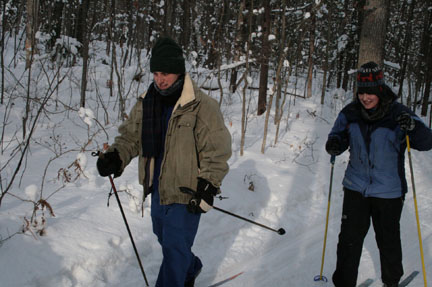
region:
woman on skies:
[314, 63, 430, 285]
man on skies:
[92, 42, 284, 285]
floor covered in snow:
[1, 26, 430, 285]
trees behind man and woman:
[1, 0, 428, 160]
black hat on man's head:
[150, 38, 183, 72]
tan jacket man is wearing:
[108, 78, 230, 208]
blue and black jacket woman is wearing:
[327, 102, 431, 198]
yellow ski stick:
[399, 132, 430, 285]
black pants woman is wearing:
[334, 190, 404, 285]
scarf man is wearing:
[141, 78, 187, 158]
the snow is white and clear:
[253, 63, 345, 280]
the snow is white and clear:
[220, 59, 295, 283]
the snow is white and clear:
[265, 160, 316, 270]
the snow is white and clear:
[249, 169, 303, 283]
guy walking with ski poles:
[77, 21, 270, 285]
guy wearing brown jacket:
[109, 33, 246, 226]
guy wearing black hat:
[127, 23, 230, 185]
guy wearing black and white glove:
[130, 31, 227, 286]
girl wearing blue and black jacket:
[319, 60, 424, 226]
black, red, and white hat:
[345, 48, 416, 124]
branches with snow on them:
[30, 75, 125, 199]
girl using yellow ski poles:
[320, 64, 430, 284]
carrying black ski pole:
[172, 171, 309, 256]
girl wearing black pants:
[310, 50, 401, 286]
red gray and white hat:
[347, 49, 395, 99]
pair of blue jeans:
[147, 201, 209, 282]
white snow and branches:
[1, 120, 73, 276]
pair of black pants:
[328, 192, 414, 285]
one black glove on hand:
[84, 138, 130, 181]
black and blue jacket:
[313, 118, 404, 214]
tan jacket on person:
[152, 117, 219, 191]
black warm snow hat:
[135, 35, 188, 76]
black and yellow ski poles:
[192, 146, 419, 281]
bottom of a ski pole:
[308, 252, 328, 285]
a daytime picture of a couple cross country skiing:
[0, 0, 430, 285]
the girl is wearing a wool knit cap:
[353, 61, 398, 112]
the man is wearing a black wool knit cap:
[148, 35, 184, 73]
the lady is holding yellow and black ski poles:
[312, 134, 336, 283]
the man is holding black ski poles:
[97, 151, 150, 286]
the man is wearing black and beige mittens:
[189, 176, 220, 214]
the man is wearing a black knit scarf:
[141, 77, 183, 151]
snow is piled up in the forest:
[1, 14, 95, 286]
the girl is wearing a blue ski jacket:
[326, 97, 430, 197]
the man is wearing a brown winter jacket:
[110, 76, 230, 203]